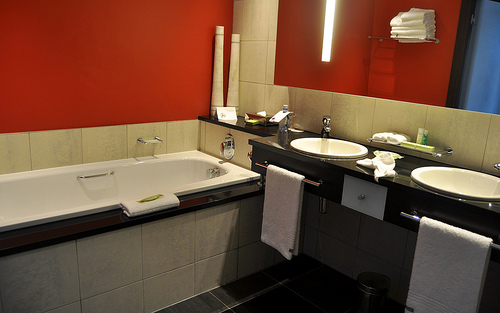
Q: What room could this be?
A: It is a bathroom.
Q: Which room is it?
A: It is a bathroom.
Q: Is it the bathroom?
A: Yes, it is the bathroom.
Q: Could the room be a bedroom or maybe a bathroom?
A: It is a bathroom.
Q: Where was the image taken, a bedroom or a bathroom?
A: It was taken at a bathroom.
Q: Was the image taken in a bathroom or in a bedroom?
A: It was taken at a bathroom.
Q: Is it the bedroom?
A: No, it is the bathroom.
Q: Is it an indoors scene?
A: Yes, it is indoors.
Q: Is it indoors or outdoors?
A: It is indoors.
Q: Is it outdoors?
A: No, it is indoors.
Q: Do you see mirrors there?
A: Yes, there is a mirror.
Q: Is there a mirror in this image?
A: Yes, there is a mirror.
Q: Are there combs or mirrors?
A: Yes, there is a mirror.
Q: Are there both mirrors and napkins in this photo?
A: No, there is a mirror but no napkins.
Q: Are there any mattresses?
A: No, there are no mattresses.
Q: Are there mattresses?
A: No, there are no mattresses.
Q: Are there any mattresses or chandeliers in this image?
A: No, there are no mattresses or chandeliers.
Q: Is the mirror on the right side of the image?
A: Yes, the mirror is on the right of the image.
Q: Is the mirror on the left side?
A: No, the mirror is on the right of the image.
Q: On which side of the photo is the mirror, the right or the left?
A: The mirror is on the right of the image.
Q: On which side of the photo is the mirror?
A: The mirror is on the right of the image.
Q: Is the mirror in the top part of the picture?
A: Yes, the mirror is in the top of the image.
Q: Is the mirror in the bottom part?
A: No, the mirror is in the top of the image.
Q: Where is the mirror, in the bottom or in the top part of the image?
A: The mirror is in the top of the image.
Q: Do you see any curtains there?
A: No, there are no curtains.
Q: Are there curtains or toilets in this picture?
A: No, there are no curtains or toilets.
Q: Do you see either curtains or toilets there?
A: No, there are no curtains or toilets.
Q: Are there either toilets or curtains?
A: No, there are no curtains or toilets.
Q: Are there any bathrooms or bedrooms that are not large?
A: No, there is a bathroom but it is large.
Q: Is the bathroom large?
A: Yes, the bathroom is large.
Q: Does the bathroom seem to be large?
A: Yes, the bathroom is large.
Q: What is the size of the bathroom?
A: The bathroom is large.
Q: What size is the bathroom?
A: The bathroom is large.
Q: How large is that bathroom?
A: The bathroom is large.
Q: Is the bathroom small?
A: No, the bathroom is large.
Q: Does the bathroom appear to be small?
A: No, the bathroom is large.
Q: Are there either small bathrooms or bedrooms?
A: No, there is a bathroom but it is large.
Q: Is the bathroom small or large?
A: The bathroom is large.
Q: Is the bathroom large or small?
A: The bathroom is large.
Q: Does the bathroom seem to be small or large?
A: The bathroom is large.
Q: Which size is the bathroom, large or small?
A: The bathroom is large.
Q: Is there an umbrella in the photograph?
A: No, there are no umbrellas.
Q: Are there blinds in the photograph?
A: No, there are no blinds.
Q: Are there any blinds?
A: No, there are no blinds.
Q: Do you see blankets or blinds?
A: No, there are no blinds or blankets.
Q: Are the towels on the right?
A: Yes, the towels are on the right of the image.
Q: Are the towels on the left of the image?
A: No, the towels are on the right of the image.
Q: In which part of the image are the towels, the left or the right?
A: The towels are on the right of the image.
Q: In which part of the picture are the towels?
A: The towels are on the right of the image.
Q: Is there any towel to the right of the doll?
A: Yes, there are towels to the right of the doll.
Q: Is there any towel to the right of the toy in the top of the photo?
A: Yes, there are towels to the right of the doll.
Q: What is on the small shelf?
A: The towels are on the shelf.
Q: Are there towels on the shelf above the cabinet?
A: Yes, there are towels on the shelf.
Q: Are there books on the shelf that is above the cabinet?
A: No, there are towels on the shelf.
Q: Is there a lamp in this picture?
A: No, there are no lamps.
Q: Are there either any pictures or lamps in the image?
A: No, there are no lamps or pictures.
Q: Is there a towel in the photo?
A: Yes, there is a towel.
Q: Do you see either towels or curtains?
A: Yes, there is a towel.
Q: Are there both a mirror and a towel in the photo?
A: Yes, there are both a towel and a mirror.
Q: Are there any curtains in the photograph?
A: No, there are no curtains.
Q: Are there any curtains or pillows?
A: No, there are no curtains or pillows.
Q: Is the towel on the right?
A: Yes, the towel is on the right of the image.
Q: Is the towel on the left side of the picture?
A: No, the towel is on the right of the image.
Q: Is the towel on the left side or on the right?
A: The towel is on the right of the image.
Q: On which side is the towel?
A: The towel is on the right of the image.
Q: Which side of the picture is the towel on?
A: The towel is on the right of the image.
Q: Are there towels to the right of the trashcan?
A: Yes, there is a towel to the right of the trashcan.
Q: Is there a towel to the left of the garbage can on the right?
A: No, the towel is to the right of the garbage can.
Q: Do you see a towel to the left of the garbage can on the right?
A: No, the towel is to the right of the garbage can.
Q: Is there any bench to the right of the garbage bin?
A: No, there is a towel to the right of the garbage bin.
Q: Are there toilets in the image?
A: No, there are no toilets.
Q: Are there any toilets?
A: No, there are no toilets.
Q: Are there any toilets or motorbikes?
A: No, there are no toilets or motorbikes.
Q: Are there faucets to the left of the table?
A: Yes, there is a faucet to the left of the table.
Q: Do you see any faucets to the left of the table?
A: Yes, there is a faucet to the left of the table.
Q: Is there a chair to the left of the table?
A: No, there is a faucet to the left of the table.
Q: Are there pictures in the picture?
A: No, there are no pictures.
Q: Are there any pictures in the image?
A: No, there are no pictures.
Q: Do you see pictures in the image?
A: No, there are no pictures.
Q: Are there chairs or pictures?
A: No, there are no pictures or chairs.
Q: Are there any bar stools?
A: No, there are no bar stools.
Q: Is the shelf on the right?
A: Yes, the shelf is on the right of the image.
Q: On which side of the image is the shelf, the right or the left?
A: The shelf is on the right of the image.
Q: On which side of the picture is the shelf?
A: The shelf is on the right of the image.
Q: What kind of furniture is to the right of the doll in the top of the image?
A: The piece of furniture is a shelf.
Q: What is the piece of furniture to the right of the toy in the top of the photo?
A: The piece of furniture is a shelf.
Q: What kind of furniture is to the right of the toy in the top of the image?
A: The piece of furniture is a shelf.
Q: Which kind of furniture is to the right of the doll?
A: The piece of furniture is a shelf.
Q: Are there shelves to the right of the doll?
A: Yes, there is a shelf to the right of the doll.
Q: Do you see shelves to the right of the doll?
A: Yes, there is a shelf to the right of the doll.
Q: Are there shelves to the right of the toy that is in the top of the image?
A: Yes, there is a shelf to the right of the doll.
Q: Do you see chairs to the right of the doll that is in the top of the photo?
A: No, there is a shelf to the right of the doll.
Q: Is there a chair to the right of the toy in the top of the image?
A: No, there is a shelf to the right of the doll.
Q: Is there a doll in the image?
A: Yes, there is a doll.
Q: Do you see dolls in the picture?
A: Yes, there is a doll.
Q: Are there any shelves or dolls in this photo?
A: Yes, there is a doll.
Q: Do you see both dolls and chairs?
A: No, there is a doll but no chairs.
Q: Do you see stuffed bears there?
A: No, there are no stuffed bears.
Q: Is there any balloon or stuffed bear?
A: No, there are no stuffed bears or balloons.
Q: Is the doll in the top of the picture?
A: Yes, the doll is in the top of the image.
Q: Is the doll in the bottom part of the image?
A: No, the doll is in the top of the image.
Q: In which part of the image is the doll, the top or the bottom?
A: The doll is in the top of the image.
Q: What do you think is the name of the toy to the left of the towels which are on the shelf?
A: The toy is a doll.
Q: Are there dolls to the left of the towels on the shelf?
A: Yes, there is a doll to the left of the towels.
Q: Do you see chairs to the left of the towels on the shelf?
A: No, there is a doll to the left of the towels.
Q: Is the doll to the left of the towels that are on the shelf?
A: Yes, the doll is to the left of the towels.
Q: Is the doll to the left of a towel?
A: Yes, the doll is to the left of a towel.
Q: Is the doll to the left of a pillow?
A: No, the doll is to the left of a towel.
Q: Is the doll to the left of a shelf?
A: Yes, the doll is to the left of a shelf.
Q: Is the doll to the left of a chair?
A: No, the doll is to the left of a shelf.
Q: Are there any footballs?
A: No, there are no footballs.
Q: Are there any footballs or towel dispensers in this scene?
A: No, there are no footballs or towel dispensers.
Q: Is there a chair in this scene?
A: No, there are no chairs.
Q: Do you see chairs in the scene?
A: No, there are no chairs.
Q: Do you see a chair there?
A: No, there are no chairs.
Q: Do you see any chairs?
A: No, there are no chairs.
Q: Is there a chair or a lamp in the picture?
A: No, there are no chairs or lamps.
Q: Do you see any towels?
A: Yes, there is a towel.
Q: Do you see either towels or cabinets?
A: Yes, there is a towel.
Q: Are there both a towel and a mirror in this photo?
A: Yes, there are both a towel and a mirror.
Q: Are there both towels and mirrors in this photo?
A: Yes, there are both a towel and a mirror.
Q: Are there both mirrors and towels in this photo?
A: Yes, there are both a towel and a mirror.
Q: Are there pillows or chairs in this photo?
A: No, there are no chairs or pillows.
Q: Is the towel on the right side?
A: Yes, the towel is on the right of the image.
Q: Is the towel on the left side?
A: No, the towel is on the right of the image.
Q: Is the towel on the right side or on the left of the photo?
A: The towel is on the right of the image.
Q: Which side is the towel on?
A: The towel is on the right of the image.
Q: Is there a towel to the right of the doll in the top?
A: Yes, there is a towel to the right of the doll.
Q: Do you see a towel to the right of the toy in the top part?
A: Yes, there is a towel to the right of the doll.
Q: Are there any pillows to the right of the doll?
A: No, there is a towel to the right of the doll.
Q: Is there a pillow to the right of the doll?
A: No, there is a towel to the right of the doll.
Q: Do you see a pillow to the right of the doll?
A: No, there is a towel to the right of the doll.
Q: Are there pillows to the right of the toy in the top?
A: No, there is a towel to the right of the doll.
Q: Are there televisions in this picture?
A: No, there are no televisions.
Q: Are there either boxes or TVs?
A: No, there are no TVs or boxes.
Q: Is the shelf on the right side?
A: Yes, the shelf is on the right of the image.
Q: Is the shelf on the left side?
A: No, the shelf is on the right of the image.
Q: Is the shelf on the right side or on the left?
A: The shelf is on the right of the image.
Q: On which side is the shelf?
A: The shelf is on the right of the image.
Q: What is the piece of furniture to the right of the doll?
A: The piece of furniture is a shelf.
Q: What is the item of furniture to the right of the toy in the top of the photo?
A: The piece of furniture is a shelf.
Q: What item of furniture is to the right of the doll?
A: The piece of furniture is a shelf.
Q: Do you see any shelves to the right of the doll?
A: Yes, there is a shelf to the right of the doll.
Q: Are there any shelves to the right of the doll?
A: Yes, there is a shelf to the right of the doll.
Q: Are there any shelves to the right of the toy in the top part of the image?
A: Yes, there is a shelf to the right of the doll.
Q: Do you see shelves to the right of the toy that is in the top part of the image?
A: Yes, there is a shelf to the right of the doll.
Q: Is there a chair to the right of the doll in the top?
A: No, there is a shelf to the right of the doll.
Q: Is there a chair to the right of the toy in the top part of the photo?
A: No, there is a shelf to the right of the doll.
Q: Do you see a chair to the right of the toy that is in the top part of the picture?
A: No, there is a shelf to the right of the doll.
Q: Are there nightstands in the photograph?
A: No, there are no nightstands.